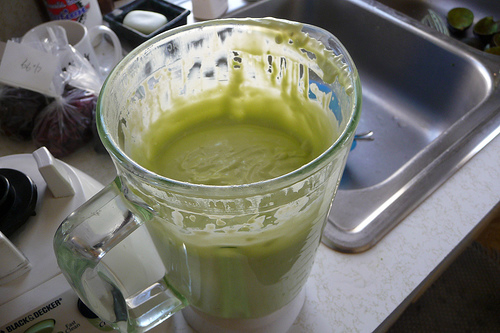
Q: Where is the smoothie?
A: In the blender.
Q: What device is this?
A: Blender.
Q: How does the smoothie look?
A: Green and thick.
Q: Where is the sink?
A: By the blender.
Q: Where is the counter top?
A: Beneath the blender.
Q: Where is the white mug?
A: Behind the blender.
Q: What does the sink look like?
A: It is silver.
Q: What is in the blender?
A: Green paste.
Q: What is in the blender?
A: A green cream.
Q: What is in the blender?
A: A green cream.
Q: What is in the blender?
A: A green cream.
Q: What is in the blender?
A: A green cream.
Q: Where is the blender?
A: On the table.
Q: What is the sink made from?
A: It is made from steel.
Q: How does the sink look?
A: It is silver and made of steel.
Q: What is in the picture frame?
A: The sink.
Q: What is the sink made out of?
A: Steel.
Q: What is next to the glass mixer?
A: A steel sink.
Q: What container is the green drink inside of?
A: A mixer.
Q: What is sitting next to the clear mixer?
A: White blender base.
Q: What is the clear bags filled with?
A: Fruit or berries.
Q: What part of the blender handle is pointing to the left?
A: It's handle.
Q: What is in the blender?
A: Avocado.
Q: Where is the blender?
A: On the counter.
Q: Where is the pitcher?
A: On a counter.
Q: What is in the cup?
A: A drink.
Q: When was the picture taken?
A: Daytime.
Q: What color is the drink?
A: Green.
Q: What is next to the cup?
A: A sink.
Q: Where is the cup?
A: The counter.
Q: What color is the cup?
A: Clear.